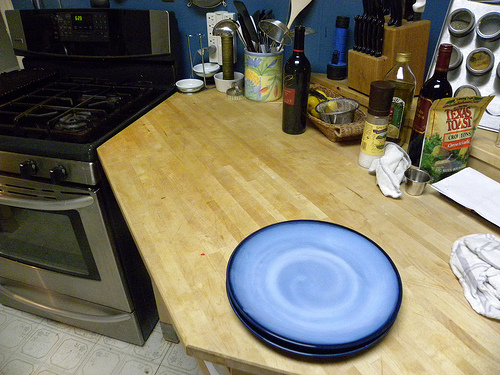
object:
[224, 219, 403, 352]
plate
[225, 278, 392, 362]
plate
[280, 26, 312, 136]
wine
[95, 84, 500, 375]
counter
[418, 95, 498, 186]
crouton bag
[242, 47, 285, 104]
utensil holder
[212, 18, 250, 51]
soup spoon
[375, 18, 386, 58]
knife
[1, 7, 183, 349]
stove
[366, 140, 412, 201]
towel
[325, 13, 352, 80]
flashlight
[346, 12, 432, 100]
knife block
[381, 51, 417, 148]
olive oil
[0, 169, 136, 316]
door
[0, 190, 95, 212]
handle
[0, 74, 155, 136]
burner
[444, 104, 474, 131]
lettering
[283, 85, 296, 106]
label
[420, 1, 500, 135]
spice rack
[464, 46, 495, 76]
cannister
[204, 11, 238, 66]
outlet strip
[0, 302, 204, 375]
floor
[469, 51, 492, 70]
herbs